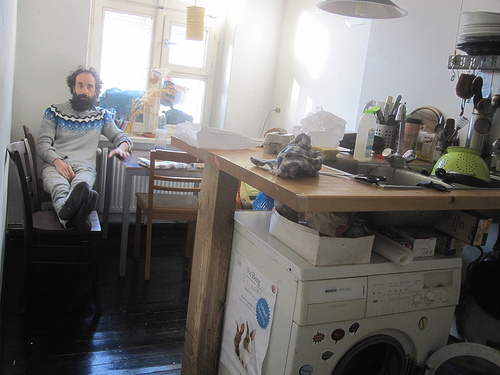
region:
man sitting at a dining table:
[21, 46, 139, 274]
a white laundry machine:
[232, 212, 480, 373]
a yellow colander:
[430, 138, 492, 185]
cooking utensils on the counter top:
[365, 91, 407, 162]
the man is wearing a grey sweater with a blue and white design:
[36, 99, 130, 167]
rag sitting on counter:
[249, 131, 326, 181]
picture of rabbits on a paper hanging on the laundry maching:
[227, 314, 258, 371]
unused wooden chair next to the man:
[132, 141, 207, 301]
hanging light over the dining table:
[180, 0, 225, 47]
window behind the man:
[95, 5, 236, 130]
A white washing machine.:
[195, 209, 498, 373]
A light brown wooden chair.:
[139, 143, 212, 283]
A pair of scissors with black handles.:
[322, 172, 388, 185]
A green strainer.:
[431, 145, 493, 182]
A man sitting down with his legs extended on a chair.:
[9, 64, 136, 310]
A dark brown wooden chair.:
[6, 133, 106, 320]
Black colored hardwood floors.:
[1, 222, 194, 372]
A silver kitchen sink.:
[321, 151, 498, 188]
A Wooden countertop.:
[172, 123, 497, 214]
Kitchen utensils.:
[367, 92, 408, 150]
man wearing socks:
[58, 183, 105, 230]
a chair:
[146, 171, 191, 222]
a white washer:
[306, 278, 461, 368]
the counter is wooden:
[299, 180, 353, 207]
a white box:
[298, 233, 344, 261]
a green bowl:
[443, 152, 479, 174]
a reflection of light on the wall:
[292, 12, 333, 74]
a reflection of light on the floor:
[72, 321, 142, 373]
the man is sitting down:
[23, 74, 126, 229]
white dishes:
[461, 8, 495, 42]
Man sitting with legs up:
[21, 50, 144, 275]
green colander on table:
[421, 137, 498, 197]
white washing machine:
[219, 202, 474, 374]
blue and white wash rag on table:
[236, 127, 351, 206]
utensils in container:
[344, 78, 416, 180]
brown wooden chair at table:
[123, 129, 224, 286]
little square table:
[103, 121, 233, 316]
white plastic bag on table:
[161, 102, 267, 176]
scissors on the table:
[315, 145, 392, 210]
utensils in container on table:
[431, 105, 471, 183]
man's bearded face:
[68, 71, 100, 110]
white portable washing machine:
[220, 255, 471, 371]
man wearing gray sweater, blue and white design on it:
[40, 65, 130, 170]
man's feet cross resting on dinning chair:
[36, 157, 92, 227]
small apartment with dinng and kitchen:
[0, 15, 497, 370]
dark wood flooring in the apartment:
[5, 231, 185, 366]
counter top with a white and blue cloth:
[215, 130, 345, 200]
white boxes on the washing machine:
[270, 206, 442, 263]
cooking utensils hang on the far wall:
[445, 73, 498, 145]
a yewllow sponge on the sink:
[316, 145, 343, 160]